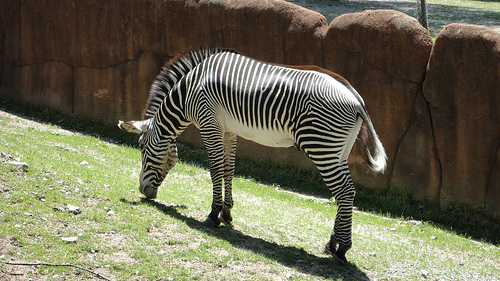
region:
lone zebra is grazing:
[115, 46, 389, 260]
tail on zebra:
[358, 107, 388, 173]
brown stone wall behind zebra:
[0, 0, 499, 210]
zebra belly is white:
[219, 108, 294, 154]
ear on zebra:
[117, 119, 149, 134]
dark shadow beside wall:
[1, 95, 498, 243]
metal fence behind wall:
[294, 0, 499, 35]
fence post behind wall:
[419, 1, 429, 29]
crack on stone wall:
[416, 88, 447, 207]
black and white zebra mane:
[137, 45, 232, 117]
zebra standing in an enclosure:
[112, 31, 398, 257]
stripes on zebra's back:
[200, 72, 298, 115]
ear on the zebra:
[117, 110, 148, 141]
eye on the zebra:
[135, 137, 150, 153]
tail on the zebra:
[352, 87, 382, 178]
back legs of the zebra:
[315, 163, 362, 258]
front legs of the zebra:
[203, 140, 240, 238]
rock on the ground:
[57, 190, 82, 221]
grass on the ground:
[45, 133, 72, 168]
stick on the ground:
[7, 250, 72, 277]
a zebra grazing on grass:
[109, 40, 401, 263]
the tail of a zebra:
[357, 99, 390, 176]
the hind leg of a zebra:
[305, 129, 357, 269]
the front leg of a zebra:
[201, 119, 238, 226]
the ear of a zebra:
[112, 115, 146, 139]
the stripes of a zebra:
[221, 69, 273, 97]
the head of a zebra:
[115, 115, 182, 200]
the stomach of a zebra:
[242, 122, 287, 151]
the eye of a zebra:
[134, 135, 149, 151]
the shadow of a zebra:
[184, 215, 396, 277]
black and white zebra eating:
[115, 43, 387, 260]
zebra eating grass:
[114, 43, 385, 263]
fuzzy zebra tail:
[359, 106, 386, 171]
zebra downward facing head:
[116, 113, 179, 200]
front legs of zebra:
[197, 127, 237, 231]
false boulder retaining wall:
[4, 1, 498, 84]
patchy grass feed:
[11, 128, 129, 274]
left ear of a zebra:
[117, 117, 148, 134]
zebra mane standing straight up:
[138, 44, 220, 119]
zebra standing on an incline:
[114, 43, 386, 265]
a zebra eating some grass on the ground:
[115, 45, 382, 255]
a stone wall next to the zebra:
[2, 3, 498, 223]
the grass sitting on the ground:
[2, 118, 484, 278]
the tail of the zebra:
[353, 121, 388, 173]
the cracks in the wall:
[380, 83, 450, 201]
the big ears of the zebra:
[111, 116, 149, 136]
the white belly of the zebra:
[222, 115, 294, 151]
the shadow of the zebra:
[149, 203, 361, 280]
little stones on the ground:
[51, 179, 115, 219]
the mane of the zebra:
[144, 45, 219, 119]